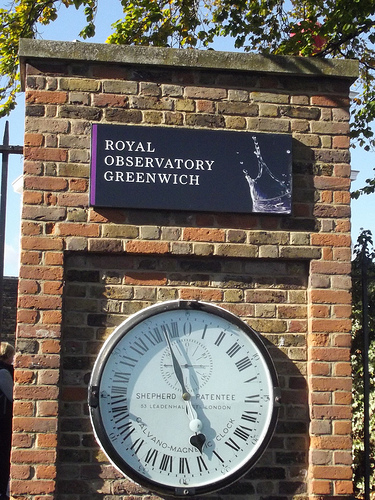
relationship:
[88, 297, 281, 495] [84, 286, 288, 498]
clock with border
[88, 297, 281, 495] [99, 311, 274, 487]
clock with face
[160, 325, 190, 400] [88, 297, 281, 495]
minute hand of clock